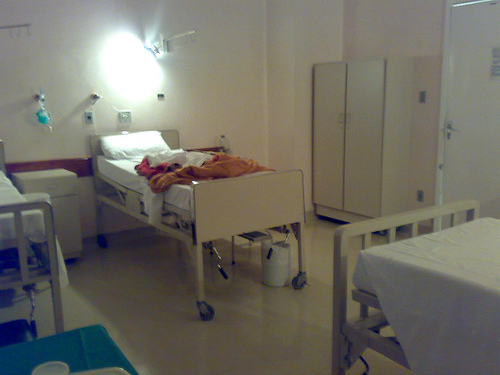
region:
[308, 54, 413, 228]
A beige closed cabinet in the right corner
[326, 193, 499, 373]
The end of a hospital bed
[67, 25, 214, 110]
A light shining on the wall making a circle of light on it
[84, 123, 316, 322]
A hospital bed with clothes on it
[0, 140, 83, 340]
A partial view of another hospital bed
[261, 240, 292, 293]
A white object underneath the hospital bed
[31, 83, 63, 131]
An object hanging on the wall with blue liquid in it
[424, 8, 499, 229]
A closed white door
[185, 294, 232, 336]
A wheel on the hospital bed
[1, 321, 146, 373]
The edge of blue cloth with a white object on it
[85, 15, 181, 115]
the light is on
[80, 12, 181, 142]
the light is white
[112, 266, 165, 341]
the floor is white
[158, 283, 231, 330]
the wheels are round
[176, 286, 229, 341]
the wheels are black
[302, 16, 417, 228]
the cabinet is white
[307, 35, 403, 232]
the cabinet is closed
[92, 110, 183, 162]
the pillow is white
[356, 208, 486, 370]
the sheet is white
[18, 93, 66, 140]
the IV is blue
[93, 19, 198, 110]
light on wall over hospital bed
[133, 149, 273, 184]
orange blanket on hospital bed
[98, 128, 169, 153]
pillow on hospital bed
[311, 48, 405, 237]
locker area in hospital room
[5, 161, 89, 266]
night stand in hospital room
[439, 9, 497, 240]
Door to hospital room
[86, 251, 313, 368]
Floor of hospital room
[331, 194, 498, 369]
hospital bed in front of hospital bed with light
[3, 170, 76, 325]
hospital bed to the left of hospital bed with light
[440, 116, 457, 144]
door lever of hospital room door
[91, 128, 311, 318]
bed in the hospital room.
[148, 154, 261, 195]
orange blanket on the bed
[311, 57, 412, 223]
closet with two doors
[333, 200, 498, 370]
foot of the bed in the corner on the right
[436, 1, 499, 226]
white door into the room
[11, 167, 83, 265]
night stand next to bed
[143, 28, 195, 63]
light fixture on wall above the bed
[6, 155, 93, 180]
red stripe on the wall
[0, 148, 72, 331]
bed on the left of the picture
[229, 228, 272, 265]
footstool next to bed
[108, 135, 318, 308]
hospital bed is white and empty